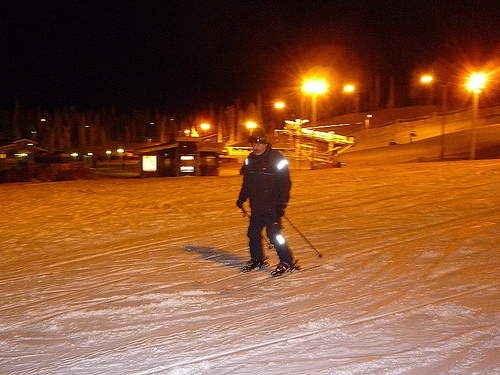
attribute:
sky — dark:
[16, 15, 223, 85]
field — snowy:
[4, 174, 495, 374]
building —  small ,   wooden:
[104, 108, 372, 212]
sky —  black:
[4, 0, 490, 130]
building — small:
[126, 132, 228, 181]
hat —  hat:
[246, 135, 273, 144]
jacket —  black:
[239, 151, 295, 213]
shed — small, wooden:
[127, 136, 222, 173]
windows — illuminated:
[139, 151, 201, 175]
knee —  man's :
[267, 232, 279, 245]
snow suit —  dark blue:
[234, 147, 294, 262]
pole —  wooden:
[462, 96, 484, 161]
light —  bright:
[458, 62, 490, 95]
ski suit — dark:
[236, 142, 294, 266]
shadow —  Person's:
[178, 240, 251, 276]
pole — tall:
[310, 95, 320, 167]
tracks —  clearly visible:
[1, 213, 243, 279]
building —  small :
[114, 134, 239, 192]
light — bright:
[462, 66, 493, 93]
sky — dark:
[7, 5, 496, 161]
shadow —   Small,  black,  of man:
[177, 223, 264, 278]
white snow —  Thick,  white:
[231, 326, 338, 371]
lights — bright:
[289, 67, 499, 105]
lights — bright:
[192, 100, 285, 130]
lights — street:
[293, 64, 332, 106]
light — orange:
[458, 66, 491, 94]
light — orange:
[417, 69, 437, 81]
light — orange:
[294, 69, 331, 99]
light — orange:
[339, 77, 360, 102]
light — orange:
[269, 98, 288, 112]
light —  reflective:
[264, 159, 305, 181]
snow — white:
[12, 199, 482, 372]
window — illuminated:
[15, 149, 33, 159]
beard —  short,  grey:
[250, 148, 266, 156]